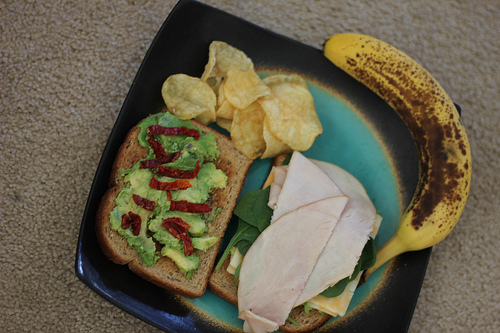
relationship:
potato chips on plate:
[162, 43, 324, 162] [73, 0, 459, 330]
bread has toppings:
[90, 103, 391, 331] [103, 109, 381, 324]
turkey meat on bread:
[259, 199, 350, 299] [212, 262, 235, 298]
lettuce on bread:
[237, 205, 264, 220] [153, 269, 185, 289]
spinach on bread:
[100, 106, 239, 280] [75, 122, 259, 292]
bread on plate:
[91, 109, 253, 297] [52, 14, 446, 326]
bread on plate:
[209, 256, 331, 332] [52, 14, 446, 326]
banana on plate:
[316, 27, 474, 292] [52, 14, 446, 326]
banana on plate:
[316, 27, 474, 292] [118, 7, 437, 329]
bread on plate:
[91, 109, 253, 297] [73, 0, 459, 330]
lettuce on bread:
[237, 205, 264, 220] [91, 109, 253, 297]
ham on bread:
[228, 149, 379, 331] [209, 256, 331, 332]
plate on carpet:
[73, 0, 459, 330] [1, 0, 499, 331]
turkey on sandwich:
[236, 151, 379, 331] [102, 124, 409, 330]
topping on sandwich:
[118, 126, 212, 256] [102, 124, 409, 330]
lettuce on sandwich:
[237, 205, 264, 220] [102, 124, 409, 330]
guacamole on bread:
[109, 111, 229, 279] [88, 113, 270, 297]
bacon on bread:
[121, 125, 206, 258] [88, 113, 270, 297]